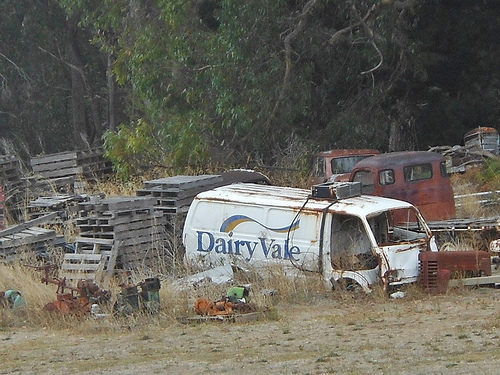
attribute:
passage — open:
[5, 289, 495, 366]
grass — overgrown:
[166, 313, 368, 371]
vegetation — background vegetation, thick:
[63, 0, 498, 184]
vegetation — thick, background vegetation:
[1, 0, 136, 166]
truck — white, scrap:
[178, 164, 441, 296]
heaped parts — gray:
[4, 148, 186, 288]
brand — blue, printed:
[195, 228, 299, 264]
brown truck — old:
[348, 149, 498, 249]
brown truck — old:
[307, 143, 384, 190]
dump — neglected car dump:
[0, 125, 498, 345]